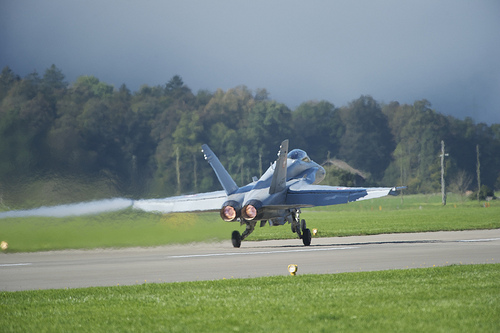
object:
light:
[287, 263, 297, 274]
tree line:
[1, 64, 499, 200]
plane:
[119, 137, 407, 249]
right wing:
[286, 183, 408, 205]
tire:
[231, 229, 244, 248]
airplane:
[132, 138, 407, 247]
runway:
[0, 228, 499, 292]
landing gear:
[231, 230, 242, 247]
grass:
[0, 262, 498, 331]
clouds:
[0, 0, 499, 126]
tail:
[197, 143, 239, 195]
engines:
[221, 199, 243, 222]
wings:
[288, 183, 410, 206]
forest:
[0, 61, 499, 210]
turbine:
[238, 198, 265, 222]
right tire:
[299, 226, 311, 245]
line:
[1, 262, 31, 267]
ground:
[1, 192, 498, 331]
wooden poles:
[440, 140, 445, 206]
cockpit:
[287, 147, 305, 161]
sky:
[0, 0, 499, 127]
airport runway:
[0, 227, 498, 291]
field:
[0, 264, 499, 332]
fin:
[199, 143, 238, 195]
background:
[2, 0, 499, 332]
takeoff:
[130, 139, 407, 248]